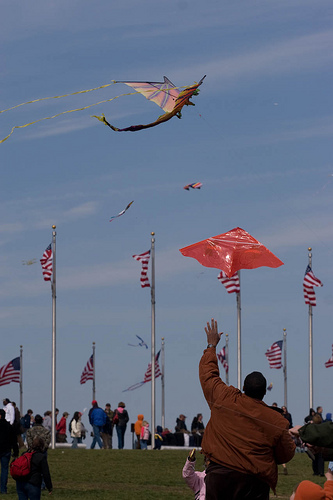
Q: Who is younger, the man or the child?
A: The child is younger than the man.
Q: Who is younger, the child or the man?
A: The child is younger than the man.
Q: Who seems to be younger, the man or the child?
A: The child is younger than the man.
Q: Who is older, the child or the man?
A: The man is older than the child.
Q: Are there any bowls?
A: No, there are no bowls.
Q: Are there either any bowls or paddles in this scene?
A: No, there are no bowls or paddles.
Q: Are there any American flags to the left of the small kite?
A: Yes, there is an American flag to the left of the kite.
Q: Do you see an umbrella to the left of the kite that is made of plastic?
A: No, there is an American flag to the left of the kite.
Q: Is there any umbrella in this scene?
A: No, there are no umbrellas.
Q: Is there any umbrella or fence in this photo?
A: No, there are no umbrellas or fences.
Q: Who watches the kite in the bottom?
A: The people watch the kite.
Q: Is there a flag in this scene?
A: Yes, there is a flag.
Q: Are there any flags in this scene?
A: Yes, there is a flag.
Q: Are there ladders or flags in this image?
A: Yes, there is a flag.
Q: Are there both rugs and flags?
A: No, there is a flag but no rugs.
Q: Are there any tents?
A: No, there are no tents.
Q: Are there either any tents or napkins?
A: No, there are no tents or napkins.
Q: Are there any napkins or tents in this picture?
A: No, there are no tents or napkins.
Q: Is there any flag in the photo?
A: Yes, there is a flag.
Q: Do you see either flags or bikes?
A: Yes, there is a flag.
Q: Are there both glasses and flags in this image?
A: No, there is a flag but no glasses.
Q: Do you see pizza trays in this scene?
A: No, there are no pizza trays.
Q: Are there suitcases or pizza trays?
A: No, there are no pizza trays or suitcases.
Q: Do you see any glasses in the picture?
A: No, there are no glasses.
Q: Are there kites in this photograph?
A: Yes, there is a kite.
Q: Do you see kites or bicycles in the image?
A: Yes, there is a kite.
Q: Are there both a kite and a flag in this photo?
A: Yes, there are both a kite and a flag.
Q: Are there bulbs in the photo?
A: No, there are no bulbs.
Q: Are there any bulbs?
A: No, there are no bulbs.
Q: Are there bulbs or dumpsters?
A: No, there are no bulbs or dumpsters.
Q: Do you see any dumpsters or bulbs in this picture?
A: No, there are no bulbs or dumpsters.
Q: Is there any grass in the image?
A: Yes, there is grass.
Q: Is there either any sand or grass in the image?
A: Yes, there is grass.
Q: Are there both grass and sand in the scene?
A: No, there is grass but no sand.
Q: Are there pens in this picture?
A: No, there are no pens.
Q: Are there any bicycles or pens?
A: No, there are no pens or bicycles.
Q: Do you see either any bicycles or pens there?
A: No, there are no pens or bicycles.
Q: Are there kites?
A: Yes, there is a kite.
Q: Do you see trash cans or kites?
A: Yes, there is a kite.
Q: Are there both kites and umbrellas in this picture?
A: No, there is a kite but no umbrellas.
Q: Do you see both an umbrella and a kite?
A: No, there is a kite but no umbrellas.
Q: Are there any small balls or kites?
A: Yes, there is a small kite.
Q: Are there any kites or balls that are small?
A: Yes, the kite is small.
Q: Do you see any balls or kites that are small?
A: Yes, the kite is small.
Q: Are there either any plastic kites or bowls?
A: Yes, there is a plastic kite.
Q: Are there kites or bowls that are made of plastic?
A: Yes, the kite is made of plastic.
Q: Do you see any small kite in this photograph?
A: Yes, there is a small kite.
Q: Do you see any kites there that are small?
A: Yes, there is a kite that is small.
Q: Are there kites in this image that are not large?
A: Yes, there is a small kite.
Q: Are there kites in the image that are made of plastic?
A: Yes, there is a kite that is made of plastic.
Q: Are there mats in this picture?
A: No, there are no mats.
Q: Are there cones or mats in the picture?
A: No, there are no mats or cones.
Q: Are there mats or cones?
A: No, there are no mats or cones.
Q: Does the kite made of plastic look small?
A: Yes, the kite is small.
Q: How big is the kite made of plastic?
A: The kite is small.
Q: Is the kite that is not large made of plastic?
A: Yes, the kite is made of plastic.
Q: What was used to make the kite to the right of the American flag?
A: The kite is made of plastic.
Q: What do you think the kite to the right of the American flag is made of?
A: The kite is made of plastic.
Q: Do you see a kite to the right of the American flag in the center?
A: Yes, there is a kite to the right of the American flag.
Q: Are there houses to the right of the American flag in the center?
A: No, there is a kite to the right of the American flag.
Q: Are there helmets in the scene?
A: No, there are no helmets.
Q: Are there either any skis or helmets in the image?
A: No, there are no helmets or skis.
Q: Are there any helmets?
A: No, there are no helmets.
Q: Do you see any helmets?
A: No, there are no helmets.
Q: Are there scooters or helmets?
A: No, there are no helmets or scooters.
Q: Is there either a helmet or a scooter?
A: No, there are no helmets or scooters.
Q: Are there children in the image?
A: Yes, there is a child.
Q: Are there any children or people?
A: Yes, there is a child.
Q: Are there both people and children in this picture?
A: Yes, there are both a child and people.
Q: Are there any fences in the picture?
A: No, there are no fences.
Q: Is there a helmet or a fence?
A: No, there are no fences or helmets.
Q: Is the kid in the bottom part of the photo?
A: Yes, the kid is in the bottom of the image.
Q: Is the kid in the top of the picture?
A: No, the kid is in the bottom of the image.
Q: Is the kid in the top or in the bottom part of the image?
A: The kid is in the bottom of the image.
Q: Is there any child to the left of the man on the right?
A: Yes, there is a child to the left of the man.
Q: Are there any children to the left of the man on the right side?
A: Yes, there is a child to the left of the man.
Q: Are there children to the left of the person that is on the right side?
A: Yes, there is a child to the left of the man.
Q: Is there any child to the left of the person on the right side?
A: Yes, there is a child to the left of the man.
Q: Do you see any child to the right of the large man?
A: No, the child is to the left of the man.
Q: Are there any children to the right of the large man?
A: No, the child is to the left of the man.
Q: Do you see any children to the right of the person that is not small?
A: No, the child is to the left of the man.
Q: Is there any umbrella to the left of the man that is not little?
A: No, there is a child to the left of the man.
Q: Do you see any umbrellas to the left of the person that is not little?
A: No, there is a child to the left of the man.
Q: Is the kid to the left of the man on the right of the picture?
A: Yes, the kid is to the left of the man.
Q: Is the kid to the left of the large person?
A: Yes, the kid is to the left of the man.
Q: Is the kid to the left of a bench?
A: No, the kid is to the left of the man.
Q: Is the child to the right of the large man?
A: No, the child is to the left of the man.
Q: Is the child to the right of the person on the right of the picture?
A: No, the child is to the left of the man.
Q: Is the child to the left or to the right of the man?
A: The child is to the left of the man.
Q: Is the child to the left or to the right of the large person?
A: The child is to the left of the man.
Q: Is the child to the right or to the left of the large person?
A: The child is to the left of the man.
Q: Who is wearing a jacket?
A: The kid is wearing a jacket.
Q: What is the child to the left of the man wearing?
A: The child is wearing a jacket.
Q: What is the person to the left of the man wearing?
A: The child is wearing a jacket.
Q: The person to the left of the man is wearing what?
A: The child is wearing a jacket.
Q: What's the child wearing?
A: The child is wearing a jacket.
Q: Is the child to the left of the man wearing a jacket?
A: Yes, the kid is wearing a jacket.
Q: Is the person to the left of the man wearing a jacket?
A: Yes, the kid is wearing a jacket.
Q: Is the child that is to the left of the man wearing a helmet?
A: No, the kid is wearing a jacket.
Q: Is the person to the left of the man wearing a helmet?
A: No, the kid is wearing a jacket.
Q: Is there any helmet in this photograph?
A: No, there are no helmets.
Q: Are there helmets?
A: No, there are no helmets.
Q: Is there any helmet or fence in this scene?
A: No, there are no helmets or fences.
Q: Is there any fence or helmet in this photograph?
A: No, there are no helmets or fences.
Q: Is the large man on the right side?
A: Yes, the man is on the right of the image.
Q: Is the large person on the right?
A: Yes, the man is on the right of the image.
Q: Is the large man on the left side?
A: No, the man is on the right of the image.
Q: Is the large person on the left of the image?
A: No, the man is on the right of the image.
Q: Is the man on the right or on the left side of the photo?
A: The man is on the right of the image.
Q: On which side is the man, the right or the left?
A: The man is on the right of the image.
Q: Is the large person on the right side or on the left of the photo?
A: The man is on the right of the image.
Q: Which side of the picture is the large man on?
A: The man is on the right of the image.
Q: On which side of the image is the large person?
A: The man is on the right of the image.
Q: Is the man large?
A: Yes, the man is large.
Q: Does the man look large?
A: Yes, the man is large.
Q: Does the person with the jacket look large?
A: Yes, the man is large.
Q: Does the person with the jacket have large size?
A: Yes, the man is large.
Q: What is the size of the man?
A: The man is large.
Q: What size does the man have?
A: The man has large size.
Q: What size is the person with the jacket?
A: The man is large.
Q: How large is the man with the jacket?
A: The man is large.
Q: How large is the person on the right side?
A: The man is large.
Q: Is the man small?
A: No, the man is large.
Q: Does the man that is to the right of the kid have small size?
A: No, the man is large.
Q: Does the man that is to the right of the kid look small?
A: No, the man is large.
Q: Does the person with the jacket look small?
A: No, the man is large.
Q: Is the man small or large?
A: The man is large.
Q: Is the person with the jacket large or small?
A: The man is large.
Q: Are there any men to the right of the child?
A: Yes, there is a man to the right of the child.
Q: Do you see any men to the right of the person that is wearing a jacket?
A: Yes, there is a man to the right of the child.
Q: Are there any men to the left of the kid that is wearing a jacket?
A: No, the man is to the right of the child.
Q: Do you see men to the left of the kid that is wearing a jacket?
A: No, the man is to the right of the child.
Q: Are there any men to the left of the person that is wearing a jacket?
A: No, the man is to the right of the child.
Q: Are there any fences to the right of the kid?
A: No, there is a man to the right of the kid.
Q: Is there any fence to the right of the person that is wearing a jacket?
A: No, there is a man to the right of the kid.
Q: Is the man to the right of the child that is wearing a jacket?
A: Yes, the man is to the right of the child.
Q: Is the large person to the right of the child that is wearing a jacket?
A: Yes, the man is to the right of the child.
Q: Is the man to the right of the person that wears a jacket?
A: Yes, the man is to the right of the child.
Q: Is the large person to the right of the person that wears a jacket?
A: Yes, the man is to the right of the child.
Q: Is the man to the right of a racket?
A: No, the man is to the right of the child.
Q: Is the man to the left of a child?
A: No, the man is to the right of a child.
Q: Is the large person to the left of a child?
A: No, the man is to the right of a child.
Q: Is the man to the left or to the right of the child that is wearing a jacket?
A: The man is to the right of the child.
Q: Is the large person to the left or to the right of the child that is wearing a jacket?
A: The man is to the right of the child.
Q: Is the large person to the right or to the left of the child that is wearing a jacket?
A: The man is to the right of the child.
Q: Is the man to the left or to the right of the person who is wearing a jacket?
A: The man is to the right of the child.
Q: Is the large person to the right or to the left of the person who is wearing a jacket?
A: The man is to the right of the child.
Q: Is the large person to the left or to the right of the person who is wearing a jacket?
A: The man is to the right of the child.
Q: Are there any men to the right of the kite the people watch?
A: Yes, there is a man to the right of the kite.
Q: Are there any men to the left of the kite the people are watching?
A: No, the man is to the right of the kite.